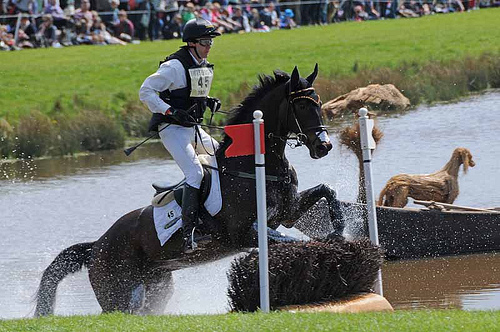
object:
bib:
[188, 67, 213, 97]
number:
[196, 75, 210, 87]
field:
[0, 0, 500, 159]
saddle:
[148, 154, 213, 211]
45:
[196, 76, 209, 89]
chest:
[166, 58, 215, 101]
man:
[137, 16, 222, 256]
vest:
[152, 50, 216, 129]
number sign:
[196, 69, 217, 91]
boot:
[181, 187, 206, 252]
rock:
[315, 82, 412, 117]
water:
[0, 88, 498, 318]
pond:
[0, 124, 500, 308]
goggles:
[198, 38, 213, 46]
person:
[110, 7, 132, 39]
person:
[272, 7, 294, 28]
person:
[259, 0, 276, 25]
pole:
[356, 105, 387, 296]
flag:
[223, 123, 266, 158]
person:
[236, 6, 274, 33]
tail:
[31, 240, 96, 320]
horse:
[25, 62, 333, 319]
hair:
[224, 70, 283, 129]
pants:
[156, 117, 226, 188]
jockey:
[138, 17, 220, 250]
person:
[74, 0, 94, 37]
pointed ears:
[288, 64, 303, 88]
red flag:
[222, 122, 267, 158]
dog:
[376, 146, 474, 207]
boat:
[342, 202, 500, 256]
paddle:
[411, 195, 488, 211]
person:
[36, 15, 61, 48]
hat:
[182, 18, 219, 40]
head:
[184, 19, 220, 58]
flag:
[366, 117, 376, 150]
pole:
[250, 108, 270, 317]